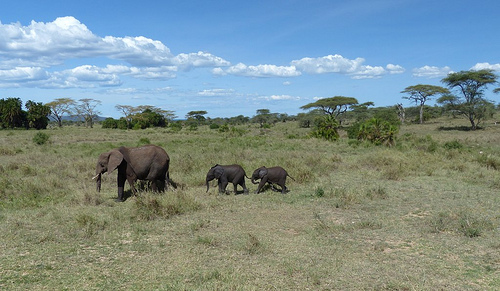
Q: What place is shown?
A: It is a field.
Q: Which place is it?
A: It is a field.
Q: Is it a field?
A: Yes, it is a field.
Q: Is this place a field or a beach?
A: It is a field.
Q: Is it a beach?
A: No, it is a field.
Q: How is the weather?
A: It is cloudy.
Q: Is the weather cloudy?
A: Yes, it is cloudy.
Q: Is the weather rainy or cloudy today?
A: It is cloudy.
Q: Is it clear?
A: No, it is cloudy.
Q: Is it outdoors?
A: Yes, it is outdoors.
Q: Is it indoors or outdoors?
A: It is outdoors.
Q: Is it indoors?
A: No, it is outdoors.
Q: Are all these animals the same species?
A: Yes, all the animals are elephants.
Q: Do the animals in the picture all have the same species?
A: Yes, all the animals are elephants.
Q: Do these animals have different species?
A: No, all the animals are elephants.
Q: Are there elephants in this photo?
A: Yes, there is an elephant.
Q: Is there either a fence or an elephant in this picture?
A: Yes, there is an elephant.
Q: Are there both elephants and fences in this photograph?
A: No, there is an elephant but no fences.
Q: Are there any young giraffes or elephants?
A: Yes, there is a young elephant.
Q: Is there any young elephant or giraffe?
A: Yes, there is a young elephant.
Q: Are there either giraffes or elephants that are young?
A: Yes, the elephant is young.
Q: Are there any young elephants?
A: Yes, there is a young elephant.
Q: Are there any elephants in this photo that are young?
A: Yes, there is an elephant that is young.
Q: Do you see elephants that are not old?
A: Yes, there is an young elephant.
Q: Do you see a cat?
A: No, there are no cats.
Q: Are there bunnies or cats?
A: No, there are no cats or bunnies.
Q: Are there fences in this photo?
A: No, there are no fences.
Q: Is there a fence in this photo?
A: No, there are no fences.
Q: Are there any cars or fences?
A: No, there are no fences or cars.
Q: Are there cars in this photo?
A: No, there are no cars.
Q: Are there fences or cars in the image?
A: No, there are no cars or fences.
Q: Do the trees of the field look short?
A: No, the trees are tall.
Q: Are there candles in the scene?
A: No, there are no candles.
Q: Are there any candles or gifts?
A: No, there are no candles or gifts.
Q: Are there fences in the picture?
A: No, there are no fences.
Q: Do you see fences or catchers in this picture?
A: No, there are no fences or catchers.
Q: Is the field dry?
A: Yes, the field is dry.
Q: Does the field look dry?
A: Yes, the field is dry.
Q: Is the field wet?
A: No, the field is dry.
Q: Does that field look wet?
A: No, the field is dry.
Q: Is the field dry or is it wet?
A: The field is dry.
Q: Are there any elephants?
A: Yes, there is an elephant.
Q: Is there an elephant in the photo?
A: Yes, there is an elephant.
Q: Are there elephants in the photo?
A: Yes, there is an elephant.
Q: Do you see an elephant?
A: Yes, there is an elephant.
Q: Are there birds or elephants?
A: Yes, there is an elephant.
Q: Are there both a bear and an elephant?
A: No, there is an elephant but no bears.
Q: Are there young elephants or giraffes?
A: Yes, there is a young elephant.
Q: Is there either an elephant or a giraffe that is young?
A: Yes, the elephant is young.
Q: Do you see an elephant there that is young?
A: Yes, there is a young elephant.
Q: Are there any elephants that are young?
A: Yes, there is an elephant that is young.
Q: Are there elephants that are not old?
A: Yes, there is an young elephant.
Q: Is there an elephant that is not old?
A: Yes, there is an young elephant.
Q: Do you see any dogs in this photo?
A: No, there are no dogs.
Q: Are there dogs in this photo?
A: No, there are no dogs.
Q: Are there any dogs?
A: No, there are no dogs.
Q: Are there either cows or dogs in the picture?
A: No, there are no dogs or cows.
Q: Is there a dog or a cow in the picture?
A: No, there are no dogs or cows.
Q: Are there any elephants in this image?
A: Yes, there is an elephant.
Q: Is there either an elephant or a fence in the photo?
A: Yes, there is an elephant.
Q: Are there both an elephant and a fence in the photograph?
A: No, there is an elephant but no fences.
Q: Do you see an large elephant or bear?
A: Yes, there is a large elephant.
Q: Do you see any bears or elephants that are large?
A: Yes, the elephant is large.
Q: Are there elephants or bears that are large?
A: Yes, the elephant is large.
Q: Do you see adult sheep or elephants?
A: Yes, there is an adult elephant.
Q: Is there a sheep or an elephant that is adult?
A: Yes, the elephant is adult.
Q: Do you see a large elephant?
A: Yes, there is a large elephant.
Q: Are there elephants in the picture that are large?
A: Yes, there is an elephant that is large.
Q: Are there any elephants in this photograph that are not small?
A: Yes, there is a large elephant.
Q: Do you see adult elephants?
A: Yes, there is an adult elephant.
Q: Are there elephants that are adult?
A: Yes, there is an elephant that is adult.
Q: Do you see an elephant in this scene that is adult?
A: Yes, there is an elephant that is adult.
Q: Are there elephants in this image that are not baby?
A: Yes, there is a adult elephant.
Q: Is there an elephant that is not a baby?
A: Yes, there is a adult elephant.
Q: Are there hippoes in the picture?
A: No, there are no hippoes.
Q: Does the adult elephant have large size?
A: Yes, the elephant is large.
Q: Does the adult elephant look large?
A: Yes, the elephant is large.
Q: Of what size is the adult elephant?
A: The elephant is large.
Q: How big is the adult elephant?
A: The elephant is large.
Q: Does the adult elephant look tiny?
A: No, the elephant is large.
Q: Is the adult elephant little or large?
A: The elephant is large.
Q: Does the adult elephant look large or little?
A: The elephant is large.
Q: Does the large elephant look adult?
A: Yes, the elephant is adult.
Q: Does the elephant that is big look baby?
A: No, the elephant is adult.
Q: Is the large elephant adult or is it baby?
A: The elephant is adult.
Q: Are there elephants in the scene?
A: Yes, there are elephants.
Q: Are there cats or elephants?
A: Yes, there are elephants.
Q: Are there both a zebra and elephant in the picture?
A: No, there are elephants but no zebras.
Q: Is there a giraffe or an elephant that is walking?
A: Yes, the elephants are walking.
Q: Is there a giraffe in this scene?
A: No, there are no giraffes.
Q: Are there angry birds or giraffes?
A: No, there are no giraffes or angry birds.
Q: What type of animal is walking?
A: The animal is elephants.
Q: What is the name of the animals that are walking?
A: The animals are elephants.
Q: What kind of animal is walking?
A: The animal is elephants.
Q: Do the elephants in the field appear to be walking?
A: Yes, the elephants are walking.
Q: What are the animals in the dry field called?
A: The animals are elephants.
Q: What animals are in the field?
A: The animals are elephants.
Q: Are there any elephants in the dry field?
A: Yes, there are elephants in the field.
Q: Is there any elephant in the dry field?
A: Yes, there are elephants in the field.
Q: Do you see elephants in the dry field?
A: Yes, there are elephants in the field.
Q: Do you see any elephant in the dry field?
A: Yes, there are elephants in the field.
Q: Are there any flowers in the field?
A: No, there are elephants in the field.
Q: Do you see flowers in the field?
A: No, there are elephants in the field.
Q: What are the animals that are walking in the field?
A: The animals are elephants.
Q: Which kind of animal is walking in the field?
A: The animals are elephants.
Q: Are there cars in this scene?
A: No, there are no cars.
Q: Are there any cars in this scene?
A: No, there are no cars.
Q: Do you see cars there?
A: No, there are no cars.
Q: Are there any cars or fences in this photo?
A: No, there are no cars or fences.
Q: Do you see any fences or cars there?
A: No, there are no cars or fences.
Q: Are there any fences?
A: No, there are no fences.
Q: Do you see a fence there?
A: No, there are no fences.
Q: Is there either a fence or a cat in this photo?
A: No, there are no fences or cats.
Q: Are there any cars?
A: No, there are no cars.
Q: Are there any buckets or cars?
A: No, there are no cars or buckets.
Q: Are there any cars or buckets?
A: No, there are no cars or buckets.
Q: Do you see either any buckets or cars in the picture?
A: No, there are no cars or buckets.